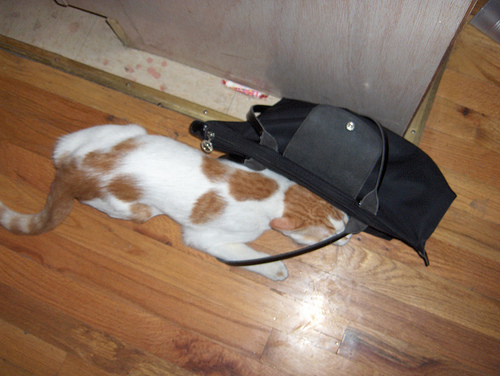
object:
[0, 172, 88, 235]
tail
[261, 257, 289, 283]
paw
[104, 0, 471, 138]
cabinet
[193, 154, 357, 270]
handle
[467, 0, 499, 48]
plastic container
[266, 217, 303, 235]
ear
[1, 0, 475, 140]
wall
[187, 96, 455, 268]
handbag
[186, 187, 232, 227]
spots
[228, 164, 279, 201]
brown spot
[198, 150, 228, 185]
brown spot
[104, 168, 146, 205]
brown spot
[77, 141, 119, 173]
brown spot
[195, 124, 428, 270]
zipper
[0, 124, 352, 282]
cat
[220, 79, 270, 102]
candy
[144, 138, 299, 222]
back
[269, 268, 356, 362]
reflection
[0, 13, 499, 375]
floor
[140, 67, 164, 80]
spots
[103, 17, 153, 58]
edge